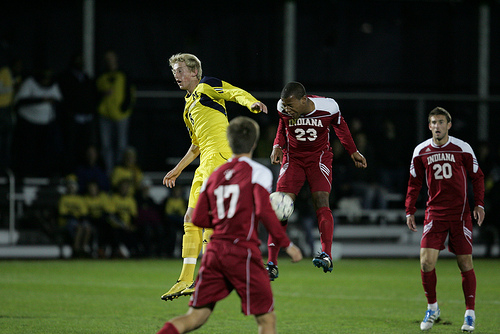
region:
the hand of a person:
[256, 182, 307, 266]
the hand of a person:
[457, 142, 492, 236]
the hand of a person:
[404, 156, 420, 231]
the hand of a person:
[326, 97, 372, 173]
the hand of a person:
[266, 121, 286, 168]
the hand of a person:
[208, 80, 272, 120]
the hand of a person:
[161, 139, 197, 186]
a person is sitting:
[61, 175, 91, 247]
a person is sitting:
[81, 176, 124, 251]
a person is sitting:
[107, 178, 144, 252]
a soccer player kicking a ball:
[270, 74, 348, 269]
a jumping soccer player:
[163, 38, 224, 291]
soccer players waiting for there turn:
[47, 161, 172, 268]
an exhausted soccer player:
[411, 98, 483, 330]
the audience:
[0, 39, 132, 184]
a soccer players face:
[165, 48, 215, 98]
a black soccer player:
[272, 70, 322, 124]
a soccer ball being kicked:
[266, 182, 295, 220]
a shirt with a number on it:
[210, 178, 250, 225]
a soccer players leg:
[409, 248, 444, 331]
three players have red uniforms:
[149, 79, 494, 332]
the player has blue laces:
[416, 310, 476, 325]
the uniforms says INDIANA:
[286, 111, 458, 172]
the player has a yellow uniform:
[147, 40, 274, 306]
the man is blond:
[162, 50, 209, 82]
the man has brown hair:
[225, 113, 266, 158]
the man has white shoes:
[416, 296, 482, 332]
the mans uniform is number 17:
[212, 180, 242, 226]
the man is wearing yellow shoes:
[158, 271, 205, 308]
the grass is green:
[1, 252, 499, 332]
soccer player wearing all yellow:
[153, 38, 233, 305]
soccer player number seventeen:
[187, 113, 304, 330]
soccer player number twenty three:
[268, 72, 367, 263]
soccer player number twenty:
[395, 86, 487, 327]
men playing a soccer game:
[101, 37, 483, 272]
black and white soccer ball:
[263, 186, 309, 227]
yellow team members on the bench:
[36, 161, 153, 250]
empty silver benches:
[341, 213, 393, 268]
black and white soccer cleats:
[308, 243, 338, 279]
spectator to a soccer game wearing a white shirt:
[16, 65, 71, 167]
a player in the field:
[148, 119, 301, 331]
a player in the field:
[408, 92, 494, 329]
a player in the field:
[255, 72, 365, 291]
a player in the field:
[148, 31, 254, 296]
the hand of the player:
[214, 77, 268, 119]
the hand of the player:
[163, 143, 195, 189]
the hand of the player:
[255, 192, 308, 275]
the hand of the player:
[333, 112, 370, 173]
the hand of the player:
[267, 125, 284, 164]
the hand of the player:
[466, 155, 492, 227]